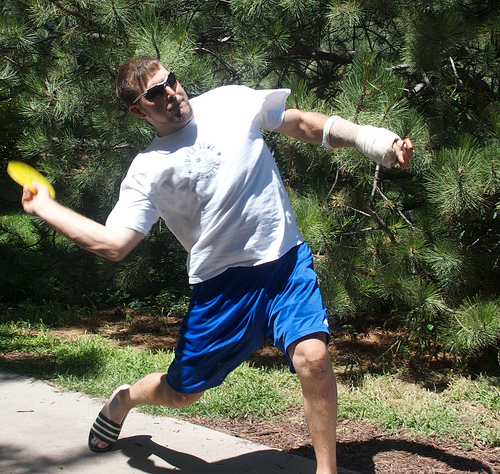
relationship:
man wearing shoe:
[127, 84, 332, 366] [87, 411, 122, 454]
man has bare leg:
[88, 50, 387, 473] [293, 364, 349, 472]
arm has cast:
[324, 116, 416, 170] [369, 132, 392, 154]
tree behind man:
[44, 27, 97, 62] [88, 50, 387, 473]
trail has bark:
[93, 318, 152, 347] [29, 307, 69, 375]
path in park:
[23, 393, 59, 464] [26, 29, 464, 474]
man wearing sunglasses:
[88, 50, 387, 473] [150, 86, 162, 103]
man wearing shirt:
[88, 50, 387, 473] [207, 110, 226, 135]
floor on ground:
[205, 419, 257, 455] [380, 381, 434, 404]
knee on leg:
[296, 357, 329, 388] [124, 379, 188, 415]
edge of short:
[5, 341, 50, 393] [172, 377, 211, 393]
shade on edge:
[360, 335, 455, 368] [5, 341, 50, 393]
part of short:
[274, 320, 297, 330] [172, 377, 211, 393]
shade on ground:
[360, 335, 455, 368] [359, 400, 449, 444]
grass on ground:
[67, 358, 111, 389] [359, 400, 449, 444]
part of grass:
[274, 320, 297, 330] [434, 338, 460, 377]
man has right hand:
[88, 50, 387, 473] [398, 140, 415, 164]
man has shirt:
[88, 50, 387, 473] [210, 96, 263, 217]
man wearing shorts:
[88, 50, 387, 473] [248, 272, 312, 305]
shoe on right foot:
[92, 440, 103, 452] [98, 387, 144, 419]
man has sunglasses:
[88, 50, 387, 473] [138, 74, 189, 99]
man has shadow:
[88, 50, 387, 473] [131, 429, 207, 473]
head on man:
[118, 56, 195, 129] [88, 50, 387, 473]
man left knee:
[193, 83, 302, 325] [172, 400, 185, 408]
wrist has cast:
[37, 198, 58, 214] [369, 132, 392, 154]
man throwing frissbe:
[88, 50, 387, 473] [4, 146, 142, 271]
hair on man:
[116, 85, 144, 101] [88, 50, 387, 473]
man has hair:
[88, 50, 387, 473] [116, 56, 159, 109]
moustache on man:
[167, 101, 183, 106] [88, 50, 387, 473]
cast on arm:
[329, 126, 340, 147] [289, 110, 315, 139]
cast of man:
[7, 159, 56, 217] [88, 50, 387, 473]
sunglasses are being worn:
[167, 77, 176, 79] [135, 92, 156, 100]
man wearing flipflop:
[88, 50, 387, 473] [110, 442, 116, 450]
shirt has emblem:
[149, 154, 182, 202] [194, 158, 217, 191]